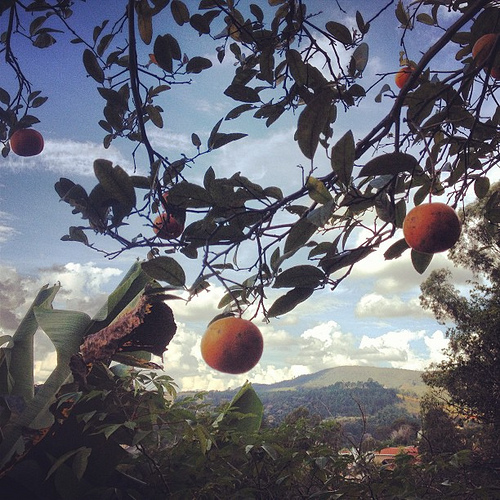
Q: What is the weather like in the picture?
A: It is cloudy.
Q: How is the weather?
A: It is cloudy.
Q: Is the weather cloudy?
A: Yes, it is cloudy.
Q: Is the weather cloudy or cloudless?
A: It is cloudy.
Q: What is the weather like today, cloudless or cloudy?
A: It is cloudy.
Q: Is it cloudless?
A: No, it is cloudy.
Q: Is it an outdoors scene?
A: Yes, it is outdoors.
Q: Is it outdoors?
A: Yes, it is outdoors.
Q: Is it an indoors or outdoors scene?
A: It is outdoors.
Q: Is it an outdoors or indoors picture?
A: It is outdoors.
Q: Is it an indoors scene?
A: No, it is outdoors.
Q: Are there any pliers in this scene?
A: No, there are no pliers.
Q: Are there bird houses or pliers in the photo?
A: No, there are no pliers or bird houses.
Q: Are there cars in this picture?
A: No, there are no cars.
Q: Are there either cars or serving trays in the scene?
A: No, there are no cars or serving trays.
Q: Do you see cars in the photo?
A: No, there are no cars.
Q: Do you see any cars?
A: No, there are no cars.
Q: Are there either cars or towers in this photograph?
A: No, there are no cars or towers.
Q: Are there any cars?
A: No, there are no cars.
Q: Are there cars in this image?
A: No, there are no cars.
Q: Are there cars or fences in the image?
A: No, there are no cars or fences.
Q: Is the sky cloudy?
A: Yes, the sky is cloudy.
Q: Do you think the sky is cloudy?
A: Yes, the sky is cloudy.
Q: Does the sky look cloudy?
A: Yes, the sky is cloudy.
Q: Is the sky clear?
A: No, the sky is cloudy.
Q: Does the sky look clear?
A: No, the sky is cloudy.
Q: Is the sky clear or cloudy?
A: The sky is cloudy.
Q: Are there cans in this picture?
A: No, there are no cans.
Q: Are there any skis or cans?
A: No, there are no cans or skis.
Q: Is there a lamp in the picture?
A: No, there are no lamps.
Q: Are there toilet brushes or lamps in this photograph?
A: No, there are no lamps or toilet brushes.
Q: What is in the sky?
A: The clouds are in the sky.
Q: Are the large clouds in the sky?
A: Yes, the clouds are in the sky.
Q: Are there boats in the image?
A: No, there are no boats.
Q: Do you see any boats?
A: No, there are no boats.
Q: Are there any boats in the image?
A: No, there are no boats.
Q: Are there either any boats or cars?
A: No, there are no boats or cars.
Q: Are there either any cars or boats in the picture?
A: No, there are no boats or cars.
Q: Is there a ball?
A: No, there are no balls.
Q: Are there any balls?
A: No, there are no balls.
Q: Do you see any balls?
A: No, there are no balls.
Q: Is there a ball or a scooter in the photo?
A: No, there are no balls or scooters.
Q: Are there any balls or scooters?
A: No, there are no balls or scooters.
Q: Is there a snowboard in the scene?
A: No, there are no snowboards.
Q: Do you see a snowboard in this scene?
A: No, there are no snowboards.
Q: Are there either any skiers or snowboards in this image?
A: No, there are no snowboards or skiers.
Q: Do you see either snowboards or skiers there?
A: No, there are no snowboards or skiers.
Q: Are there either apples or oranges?
A: Yes, there are oranges.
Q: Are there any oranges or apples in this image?
A: Yes, there are oranges.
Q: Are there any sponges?
A: No, there are no sponges.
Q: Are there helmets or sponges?
A: No, there are no sponges or helmets.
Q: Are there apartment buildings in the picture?
A: No, there are no apartment buildings.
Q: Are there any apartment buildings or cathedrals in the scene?
A: No, there are no apartment buildings or cathedrals.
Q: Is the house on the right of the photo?
A: Yes, the house is on the right of the image.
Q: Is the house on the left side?
A: No, the house is on the right of the image.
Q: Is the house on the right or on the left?
A: The house is on the right of the image.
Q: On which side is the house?
A: The house is on the right of the image.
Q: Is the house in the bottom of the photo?
A: Yes, the house is in the bottom of the image.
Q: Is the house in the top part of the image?
A: No, the house is in the bottom of the image.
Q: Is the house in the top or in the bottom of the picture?
A: The house is in the bottom of the image.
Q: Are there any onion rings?
A: No, there are no onion rings.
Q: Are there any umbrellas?
A: No, there are no umbrellas.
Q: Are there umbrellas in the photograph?
A: No, there are no umbrellas.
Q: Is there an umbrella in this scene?
A: No, there are no umbrellas.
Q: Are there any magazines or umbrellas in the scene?
A: No, there are no umbrellas or magazines.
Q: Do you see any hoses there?
A: No, there are no hoses.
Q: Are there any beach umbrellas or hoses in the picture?
A: No, there are no hoses or beach umbrellas.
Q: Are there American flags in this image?
A: No, there are no American flags.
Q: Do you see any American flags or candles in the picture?
A: No, there are no American flags or candles.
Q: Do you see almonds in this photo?
A: No, there are no almonds.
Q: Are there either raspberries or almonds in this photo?
A: No, there are no almonds or raspberries.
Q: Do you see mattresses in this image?
A: No, there are no mattresses.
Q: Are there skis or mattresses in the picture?
A: No, there are no mattresses or skis.